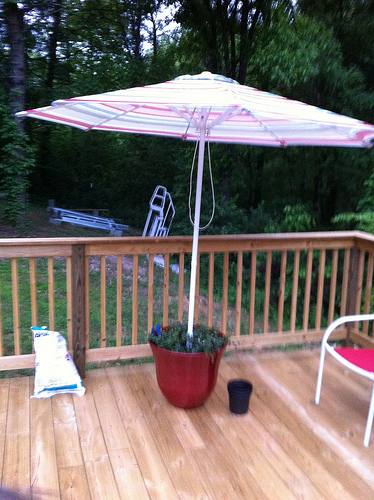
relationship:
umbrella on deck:
[11, 67, 374, 150] [0, 346, 373, 498]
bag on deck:
[30, 322, 87, 401] [0, 346, 373, 498]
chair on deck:
[312, 312, 374, 449] [0, 346, 373, 498]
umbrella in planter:
[11, 67, 374, 150] [149, 326, 230, 410]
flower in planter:
[154, 322, 166, 334] [149, 326, 230, 410]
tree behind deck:
[250, 4, 364, 229] [0, 346, 373, 498]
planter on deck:
[149, 326, 230, 410] [0, 346, 373, 498]